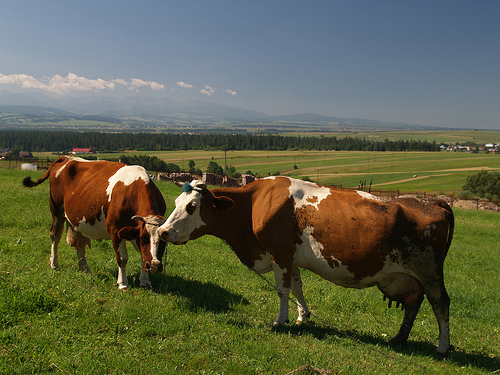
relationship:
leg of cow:
[272, 255, 291, 320] [155, 170, 454, 354]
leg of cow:
[426, 275, 450, 352] [155, 170, 454, 354]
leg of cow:
[426, 275, 451, 356] [155, 170, 454, 354]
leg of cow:
[387, 291, 425, 337] [155, 170, 454, 354]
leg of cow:
[283, 266, 309, 317] [155, 170, 454, 354]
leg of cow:
[272, 255, 289, 331] [155, 170, 454, 354]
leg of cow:
[111, 232, 126, 289] [23, 156, 165, 289]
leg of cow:
[136, 237, 151, 294] [23, 156, 165, 289]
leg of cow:
[44, 215, 63, 263] [23, 156, 165, 289]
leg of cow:
[62, 228, 91, 269] [23, 156, 165, 289]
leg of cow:
[387, 287, 424, 346] [155, 170, 454, 354]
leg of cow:
[283, 266, 315, 321] [155, 170, 454, 354]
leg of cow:
[111, 232, 127, 286] [18, 152, 177, 294]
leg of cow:
[62, 228, 93, 277] [18, 152, 177, 294]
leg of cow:
[44, 215, 64, 271] [18, 152, 177, 294]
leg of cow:
[62, 228, 91, 269] [24, 156, 182, 292]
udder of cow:
[375, 274, 421, 312] [155, 170, 454, 354]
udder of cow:
[379, 269, 415, 311] [155, 170, 454, 354]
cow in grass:
[155, 170, 454, 354] [0, 166, 499, 374]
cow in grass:
[23, 156, 165, 289] [0, 166, 499, 374]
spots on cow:
[286, 180, 333, 211] [155, 170, 454, 354]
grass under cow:
[0, 166, 499, 374] [155, 170, 454, 354]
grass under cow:
[0, 166, 499, 374] [23, 156, 165, 289]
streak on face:
[143, 212, 162, 265] [121, 211, 189, 279]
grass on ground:
[0, 166, 499, 374] [0, 129, 498, 374]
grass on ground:
[130, 300, 207, 355] [26, 273, 221, 369]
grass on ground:
[0, 166, 499, 374] [0, 237, 497, 372]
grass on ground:
[0, 166, 499, 374] [2, 152, 499, 373]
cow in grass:
[21, 154, 172, 293] [0, 166, 499, 374]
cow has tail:
[155, 170, 454, 354] [19, 153, 71, 193]